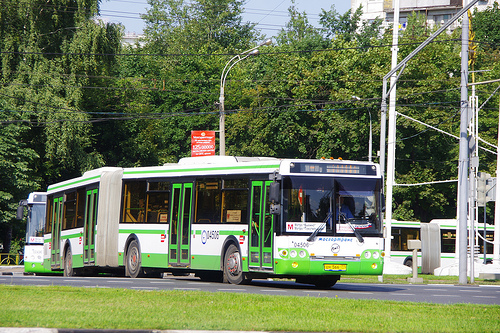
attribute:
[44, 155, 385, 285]
bus — green, white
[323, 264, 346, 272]
license plate — yellow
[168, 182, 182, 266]
door — green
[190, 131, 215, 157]
sign — red, large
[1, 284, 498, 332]
grass — green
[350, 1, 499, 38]
building — white, tall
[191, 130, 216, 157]
banner — red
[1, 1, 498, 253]
trees — green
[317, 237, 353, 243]
writing — blue